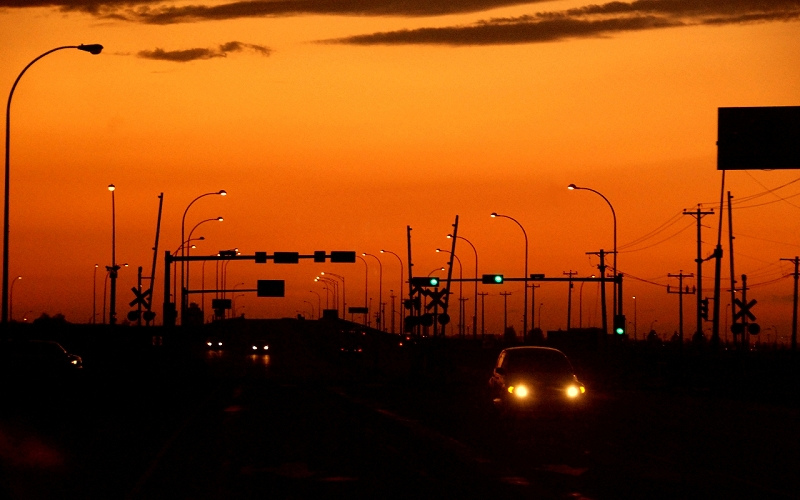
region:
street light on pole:
[562, 176, 579, 195]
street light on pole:
[487, 210, 498, 226]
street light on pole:
[442, 230, 459, 247]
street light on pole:
[375, 243, 389, 256]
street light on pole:
[357, 249, 369, 259]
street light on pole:
[215, 185, 229, 198]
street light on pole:
[210, 209, 229, 227]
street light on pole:
[102, 177, 123, 198]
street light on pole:
[82, 40, 102, 56]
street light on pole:
[86, 259, 106, 275]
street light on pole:
[566, 177, 576, 195]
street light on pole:
[486, 207, 500, 219]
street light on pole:
[442, 230, 454, 244]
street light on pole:
[431, 245, 443, 255]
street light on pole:
[317, 264, 329, 275]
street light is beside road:
[0, 40, 104, 324]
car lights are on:
[488, 341, 581, 410]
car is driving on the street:
[488, 344, 592, 416]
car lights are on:
[245, 334, 274, 352]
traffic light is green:
[416, 276, 440, 286]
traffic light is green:
[616, 313, 624, 334]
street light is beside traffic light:
[566, 181, 616, 343]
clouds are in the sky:
[0, 0, 798, 62]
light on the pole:
[99, 176, 126, 202]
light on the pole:
[205, 181, 235, 201]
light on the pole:
[472, 265, 516, 283]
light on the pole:
[349, 301, 369, 318]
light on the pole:
[592, 307, 636, 334]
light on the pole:
[243, 272, 285, 301]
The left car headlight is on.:
[508, 381, 527, 398]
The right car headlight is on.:
[564, 382, 584, 398]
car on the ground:
[425, 264, 645, 476]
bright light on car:
[493, 359, 550, 416]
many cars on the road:
[124, 286, 628, 457]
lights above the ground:
[423, 160, 644, 268]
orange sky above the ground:
[249, 71, 471, 172]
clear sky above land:
[333, 97, 465, 157]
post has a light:
[218, 188, 230, 198]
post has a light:
[104, 183, 116, 196]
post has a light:
[77, 40, 106, 56]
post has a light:
[327, 248, 363, 262]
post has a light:
[406, 279, 439, 287]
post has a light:
[480, 276, 507, 286]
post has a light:
[614, 315, 627, 337]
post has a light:
[568, 180, 578, 193]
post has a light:
[487, 208, 497, 218]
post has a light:
[444, 232, 454, 244]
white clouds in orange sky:
[484, 145, 543, 209]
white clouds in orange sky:
[555, 51, 630, 124]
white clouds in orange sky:
[164, 106, 228, 163]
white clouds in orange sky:
[292, 106, 358, 160]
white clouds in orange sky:
[249, 177, 306, 236]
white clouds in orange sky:
[27, 97, 125, 186]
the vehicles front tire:
[500, 394, 526, 431]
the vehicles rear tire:
[475, 376, 494, 405]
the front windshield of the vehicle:
[504, 345, 576, 377]